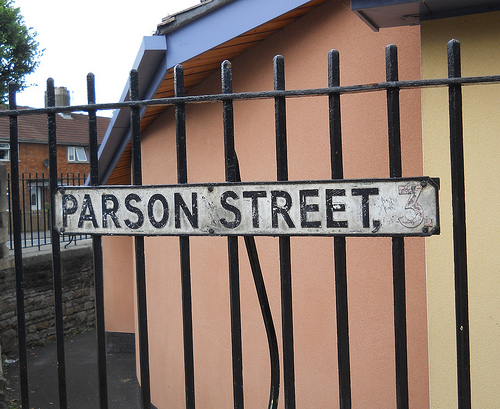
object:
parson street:
[62, 187, 379, 229]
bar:
[222, 62, 245, 409]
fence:
[0, 34, 497, 408]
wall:
[1, 140, 101, 235]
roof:
[1, 102, 112, 146]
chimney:
[45, 86, 70, 111]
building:
[79, 0, 500, 409]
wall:
[102, 3, 426, 408]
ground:
[2, 331, 140, 408]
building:
[0, 104, 112, 236]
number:
[396, 185, 425, 230]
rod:
[8, 79, 33, 408]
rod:
[445, 38, 473, 405]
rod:
[221, 58, 250, 408]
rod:
[46, 77, 70, 408]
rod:
[86, 73, 110, 408]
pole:
[2, 75, 498, 117]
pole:
[0, 176, 87, 184]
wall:
[419, 9, 499, 408]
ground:
[7, 230, 93, 258]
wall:
[1, 245, 98, 354]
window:
[68, 146, 75, 161]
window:
[1, 144, 11, 162]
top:
[1, 103, 112, 176]